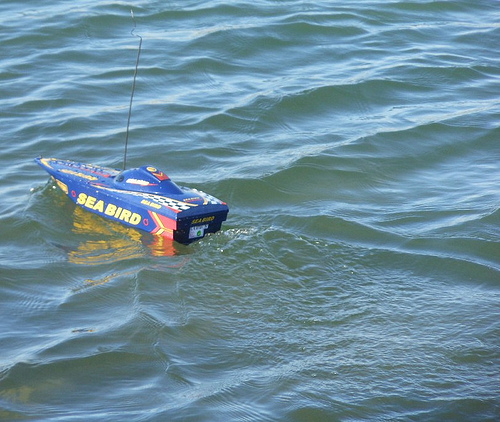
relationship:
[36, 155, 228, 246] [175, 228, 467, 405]
boat in motion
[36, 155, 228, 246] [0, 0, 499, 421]
boat floating on water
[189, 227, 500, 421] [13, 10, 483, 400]
motion on water's surface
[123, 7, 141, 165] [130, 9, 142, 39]
antenna bent near tip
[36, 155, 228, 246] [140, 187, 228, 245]
boat with designs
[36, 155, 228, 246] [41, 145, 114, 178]
boat with designs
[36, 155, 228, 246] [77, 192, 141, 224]
boat with name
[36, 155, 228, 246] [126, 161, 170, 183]
boat with designs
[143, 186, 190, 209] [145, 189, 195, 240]
checkerboard in corner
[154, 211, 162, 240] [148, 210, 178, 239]
arrow on blocks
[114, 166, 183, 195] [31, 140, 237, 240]
engine room on top of boat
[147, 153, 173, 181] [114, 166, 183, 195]
figure on top of engine room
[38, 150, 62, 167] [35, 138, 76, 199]
curve at boat tip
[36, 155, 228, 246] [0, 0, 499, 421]
boat on water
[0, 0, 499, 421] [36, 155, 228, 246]
water has large waves for boat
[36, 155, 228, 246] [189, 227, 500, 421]
boat leaving a motion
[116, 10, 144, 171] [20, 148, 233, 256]
antenna on boat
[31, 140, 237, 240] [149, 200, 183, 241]
boat with stripes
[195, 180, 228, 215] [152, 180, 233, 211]
flags are painted over engine room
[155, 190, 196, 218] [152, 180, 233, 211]
flags are painted over engine room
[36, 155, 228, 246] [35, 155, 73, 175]
boat has boat tip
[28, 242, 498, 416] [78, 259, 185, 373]
water has waves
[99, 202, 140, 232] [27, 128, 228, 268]
letter on boat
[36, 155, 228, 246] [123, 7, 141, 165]
boat has a antenna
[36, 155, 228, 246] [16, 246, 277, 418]
boat on water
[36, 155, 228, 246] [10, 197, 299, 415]
boat in water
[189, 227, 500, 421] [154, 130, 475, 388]
motion in water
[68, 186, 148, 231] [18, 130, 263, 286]
words on side of boat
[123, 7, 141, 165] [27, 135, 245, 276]
antenna sticking up out of boat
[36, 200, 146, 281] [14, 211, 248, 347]
reflection of boat in water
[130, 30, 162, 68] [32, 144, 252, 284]
tip of boat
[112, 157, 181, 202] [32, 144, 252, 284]
shape on top of boat